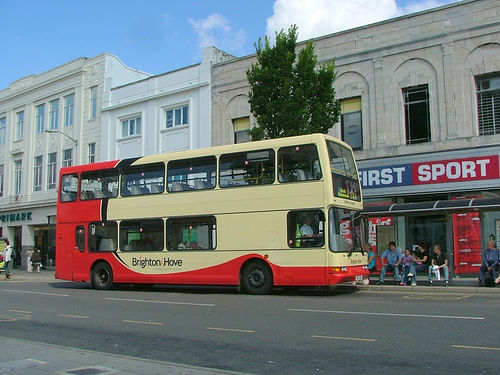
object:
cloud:
[188, 12, 247, 57]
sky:
[0, 0, 461, 90]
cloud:
[262, 0, 403, 50]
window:
[180, 103, 191, 125]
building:
[98, 45, 239, 167]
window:
[173, 108, 180, 128]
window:
[164, 107, 174, 129]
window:
[135, 115, 141, 134]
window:
[127, 118, 136, 135]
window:
[122, 118, 128, 137]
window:
[165, 214, 219, 250]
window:
[59, 171, 79, 202]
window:
[79, 169, 121, 201]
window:
[119, 160, 164, 200]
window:
[166, 155, 218, 192]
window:
[216, 146, 276, 190]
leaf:
[264, 89, 270, 97]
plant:
[244, 20, 343, 142]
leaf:
[273, 77, 280, 82]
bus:
[53, 132, 375, 296]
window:
[284, 207, 326, 249]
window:
[86, 220, 124, 252]